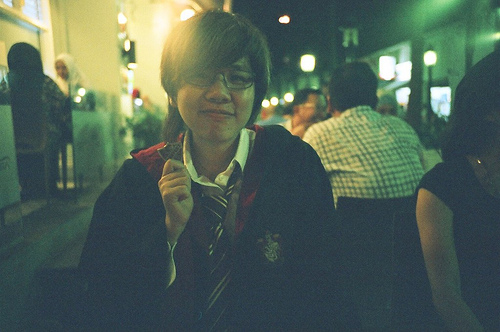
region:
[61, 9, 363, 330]
person sitting in chair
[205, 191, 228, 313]
black and white tie on shirt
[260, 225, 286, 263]
logo on side of jacket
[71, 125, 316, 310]
black and red jacket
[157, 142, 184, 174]
logo on top of jacket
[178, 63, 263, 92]
black frame glasses on face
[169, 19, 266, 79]
bowl haircut on head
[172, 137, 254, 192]
white collard shirt on person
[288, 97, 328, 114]
glasses on face of man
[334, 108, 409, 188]
white and black checkered shirt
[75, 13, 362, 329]
a woman wearing a cloak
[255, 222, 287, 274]
ensign on a cloak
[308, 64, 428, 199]
the back of a man who is sitting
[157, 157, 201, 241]
hand of a young woman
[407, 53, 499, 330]
side of a woman who is sitting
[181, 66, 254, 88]
glasses on a girls face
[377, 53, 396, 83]
a light in the distance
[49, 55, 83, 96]
woman wearing a white scarf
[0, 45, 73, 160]
back of a person who is sitting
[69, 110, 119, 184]
siding of glass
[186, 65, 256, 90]
the black glasses of a person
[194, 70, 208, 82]
the brown eye of a person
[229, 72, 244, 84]
the brown eye of a person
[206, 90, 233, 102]
the small nose of a person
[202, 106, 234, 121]
the small mouth of a person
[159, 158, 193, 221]
the closed hand of a person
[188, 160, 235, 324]
a black and white tie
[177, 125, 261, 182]
the white collar of a shirt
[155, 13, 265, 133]
the short brown hair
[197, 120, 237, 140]
the chin of a face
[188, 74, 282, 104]
black framed oval glasses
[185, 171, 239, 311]
black and white striped tie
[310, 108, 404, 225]
black and white checkered shirt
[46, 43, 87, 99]
white scarf on woman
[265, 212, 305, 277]
patch on sweater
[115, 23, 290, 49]
short black hair with bangs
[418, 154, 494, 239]
black crew shirt for woman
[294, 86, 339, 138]
man smiling sitting down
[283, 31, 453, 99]
multiple street lights lined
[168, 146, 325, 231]
white collar dress shirt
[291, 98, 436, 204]
black and white checkered shirt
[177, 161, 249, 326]
black and white striped tie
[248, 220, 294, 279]
emblem on front of black jacket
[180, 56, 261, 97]
black framed eye glasses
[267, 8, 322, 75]
hanging lights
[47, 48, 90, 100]
woman with white head scarf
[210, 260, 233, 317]
striped pattern on black tie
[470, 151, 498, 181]
metal necklace on woman's neck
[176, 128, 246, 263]
white collared shirt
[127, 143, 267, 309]
red interior lining of black jacket